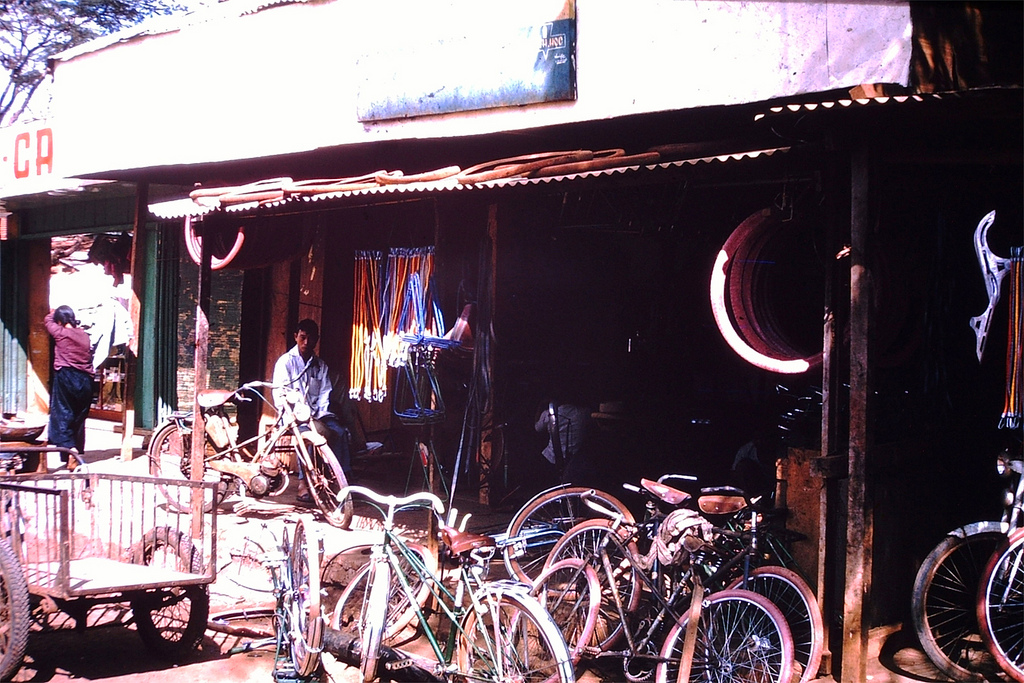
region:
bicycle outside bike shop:
[330, 473, 571, 677]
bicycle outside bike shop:
[512, 491, 798, 676]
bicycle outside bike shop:
[200, 482, 327, 670]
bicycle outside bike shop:
[143, 365, 346, 528]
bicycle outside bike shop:
[969, 526, 1018, 678]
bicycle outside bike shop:
[501, 488, 793, 676]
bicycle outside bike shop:
[324, 479, 569, 670]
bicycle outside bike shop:
[257, 505, 335, 680]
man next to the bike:
[229, 283, 392, 457]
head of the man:
[266, 291, 350, 374]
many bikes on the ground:
[291, 374, 903, 673]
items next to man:
[296, 209, 496, 413]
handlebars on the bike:
[269, 430, 484, 549]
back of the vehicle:
[5, 418, 271, 640]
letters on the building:
[0, 111, 81, 188]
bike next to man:
[118, 359, 381, 530]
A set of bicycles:
[293, 447, 809, 679]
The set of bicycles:
[249, 442, 825, 667]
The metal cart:
[1, 461, 227, 674]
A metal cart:
[5, 456, 237, 668]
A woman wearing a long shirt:
[40, 304, 129, 461]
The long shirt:
[37, 295, 110, 460]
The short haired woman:
[28, 291, 124, 460]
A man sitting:
[262, 307, 361, 482]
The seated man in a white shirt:
[255, 314, 366, 477]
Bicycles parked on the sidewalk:
[250, 465, 823, 680]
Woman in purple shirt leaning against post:
[31, 304, 107, 476]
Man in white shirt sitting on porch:
[264, 312, 364, 453]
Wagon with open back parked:
[5, 459, 217, 671]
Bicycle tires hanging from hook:
[701, 205, 876, 387]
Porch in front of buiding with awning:
[78, 155, 837, 561]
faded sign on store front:
[306, 16, 620, 112]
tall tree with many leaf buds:
[2, 3, 41, 103]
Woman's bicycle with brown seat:
[158, 385, 370, 534]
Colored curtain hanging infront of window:
[328, 240, 447, 405]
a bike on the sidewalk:
[324, 486, 555, 679]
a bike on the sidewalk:
[488, 451, 637, 676]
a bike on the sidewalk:
[640, 474, 733, 643]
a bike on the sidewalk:
[550, 471, 766, 678]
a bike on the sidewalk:
[216, 348, 344, 520]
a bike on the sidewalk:
[947, 541, 1020, 669]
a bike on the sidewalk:
[886, 471, 997, 675]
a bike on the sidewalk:
[301, 500, 450, 649]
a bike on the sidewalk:
[327, 546, 426, 636]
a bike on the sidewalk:
[526, 540, 602, 668]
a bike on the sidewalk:
[684, 493, 859, 650]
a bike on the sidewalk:
[544, 478, 681, 676]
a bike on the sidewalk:
[275, 402, 403, 510]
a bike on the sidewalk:
[918, 467, 1011, 569]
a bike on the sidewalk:
[936, 519, 1017, 618]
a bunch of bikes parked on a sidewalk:
[263, 452, 829, 680]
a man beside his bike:
[152, 313, 361, 523]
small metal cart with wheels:
[0, 459, 229, 672]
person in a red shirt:
[38, 301, 100, 467]